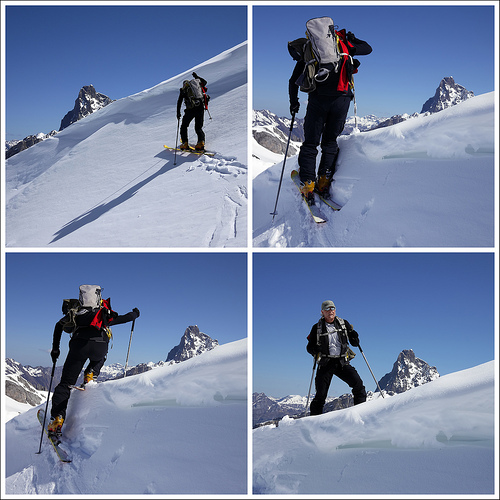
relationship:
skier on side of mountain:
[169, 70, 214, 163] [5, 35, 245, 243]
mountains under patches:
[252, 75, 474, 157] [344, 86, 482, 144]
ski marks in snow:
[168, 144, 246, 245] [192, 145, 243, 182]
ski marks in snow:
[353, 123, 498, 164] [366, 131, 466, 161]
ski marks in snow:
[255, 171, 401, 246] [296, 220, 340, 233]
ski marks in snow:
[95, 381, 246, 415] [103, 382, 230, 407]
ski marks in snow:
[259, 411, 494, 486] [301, 410, 481, 447]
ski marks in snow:
[9, 410, 127, 493] [45, 454, 82, 468]